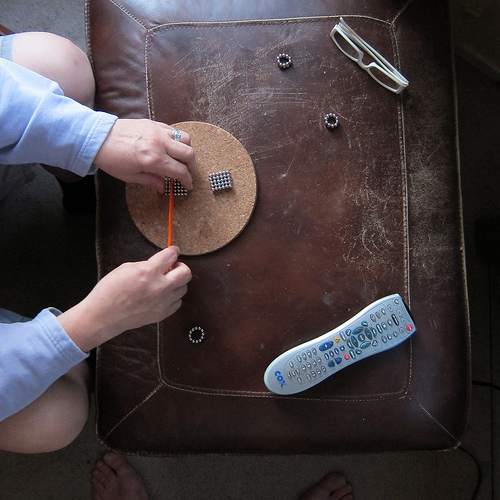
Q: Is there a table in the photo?
A: Yes, there is a table.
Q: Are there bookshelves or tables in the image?
A: Yes, there is a table.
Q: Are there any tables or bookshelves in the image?
A: Yes, there is a table.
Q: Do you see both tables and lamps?
A: No, there is a table but no lamps.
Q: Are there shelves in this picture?
A: No, there are no shelves.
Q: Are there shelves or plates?
A: No, there are no shelves or plates.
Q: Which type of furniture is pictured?
A: The furniture is a table.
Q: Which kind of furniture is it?
A: The piece of furniture is a table.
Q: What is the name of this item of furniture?
A: This is a table.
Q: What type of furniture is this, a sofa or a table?
A: This is a table.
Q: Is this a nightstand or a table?
A: This is a table.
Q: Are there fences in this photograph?
A: No, there are no fences.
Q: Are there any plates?
A: No, there are no plates.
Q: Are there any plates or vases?
A: No, there are no plates or vases.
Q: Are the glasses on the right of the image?
A: Yes, the glasses are on the right of the image.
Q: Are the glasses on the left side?
A: No, the glasses are on the right of the image.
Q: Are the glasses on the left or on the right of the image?
A: The glasses are on the right of the image.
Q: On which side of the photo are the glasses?
A: The glasses are on the right of the image.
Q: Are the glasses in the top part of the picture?
A: Yes, the glasses are in the top of the image.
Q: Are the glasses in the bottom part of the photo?
A: No, the glasses are in the top of the image.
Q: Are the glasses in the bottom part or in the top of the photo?
A: The glasses are in the top of the image.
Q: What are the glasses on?
A: The glasses are on the table.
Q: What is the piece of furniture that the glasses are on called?
A: The piece of furniture is a table.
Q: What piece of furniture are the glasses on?
A: The glasses are on the table.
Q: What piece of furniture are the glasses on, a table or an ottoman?
A: The glasses are on a table.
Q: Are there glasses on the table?
A: Yes, there are glasses on the table.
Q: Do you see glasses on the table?
A: Yes, there are glasses on the table.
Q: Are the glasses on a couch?
A: No, the glasses are on the table.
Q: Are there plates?
A: No, there are no plates.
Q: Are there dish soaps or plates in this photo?
A: No, there are no plates or dish soaps.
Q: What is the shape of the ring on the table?
A: The ring is round.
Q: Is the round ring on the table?
A: Yes, the ring is on the table.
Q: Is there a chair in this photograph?
A: No, there are no chairs.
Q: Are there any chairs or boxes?
A: No, there are no chairs or boxes.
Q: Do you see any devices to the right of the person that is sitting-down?
A: Yes, there is a device to the right of the person.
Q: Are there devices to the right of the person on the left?
A: Yes, there is a device to the right of the person.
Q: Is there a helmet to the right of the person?
A: No, there is a device to the right of the person.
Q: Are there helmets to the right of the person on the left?
A: No, there is a device to the right of the person.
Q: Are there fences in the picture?
A: No, there are no fences.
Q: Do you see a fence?
A: No, there are no fences.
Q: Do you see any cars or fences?
A: No, there are no fences or cars.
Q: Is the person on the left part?
A: Yes, the person is on the left of the image.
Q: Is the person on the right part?
A: No, the person is on the left of the image.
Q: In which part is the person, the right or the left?
A: The person is on the left of the image.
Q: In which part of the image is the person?
A: The person is on the left of the image.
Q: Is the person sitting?
A: Yes, the person is sitting.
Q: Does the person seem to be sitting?
A: Yes, the person is sitting.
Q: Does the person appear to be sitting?
A: Yes, the person is sitting.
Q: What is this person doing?
A: The person is sitting.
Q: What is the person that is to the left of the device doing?
A: The person is sitting.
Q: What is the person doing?
A: The person is sitting.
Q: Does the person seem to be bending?
A: No, the person is sitting.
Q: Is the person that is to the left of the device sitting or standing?
A: The person is sitting.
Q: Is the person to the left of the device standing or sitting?
A: The person is sitting.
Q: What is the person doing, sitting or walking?
A: The person is sitting.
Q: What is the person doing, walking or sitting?
A: The person is sitting.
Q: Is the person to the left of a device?
A: Yes, the person is to the left of a device.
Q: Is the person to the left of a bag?
A: No, the person is to the left of a device.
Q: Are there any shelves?
A: No, there are no shelves.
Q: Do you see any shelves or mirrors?
A: No, there are no shelves or mirrors.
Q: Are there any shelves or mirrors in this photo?
A: No, there are no shelves or mirrors.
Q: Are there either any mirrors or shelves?
A: No, there are no shelves or mirrors.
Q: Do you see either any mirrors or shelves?
A: No, there are no shelves or mirrors.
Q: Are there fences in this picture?
A: No, there are no fences.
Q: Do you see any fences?
A: No, there are no fences.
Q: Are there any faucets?
A: No, there are no faucets.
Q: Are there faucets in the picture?
A: No, there are no faucets.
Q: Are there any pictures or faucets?
A: No, there are no faucets or pictures.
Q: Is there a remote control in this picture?
A: Yes, there is a remote control.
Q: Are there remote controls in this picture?
A: Yes, there is a remote control.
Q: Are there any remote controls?
A: Yes, there is a remote control.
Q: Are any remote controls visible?
A: Yes, there is a remote control.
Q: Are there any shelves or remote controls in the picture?
A: Yes, there is a remote control.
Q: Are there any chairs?
A: No, there are no chairs.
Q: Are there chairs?
A: No, there are no chairs.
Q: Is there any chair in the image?
A: No, there are no chairs.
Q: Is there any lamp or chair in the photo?
A: No, there are no chairs or lamps.